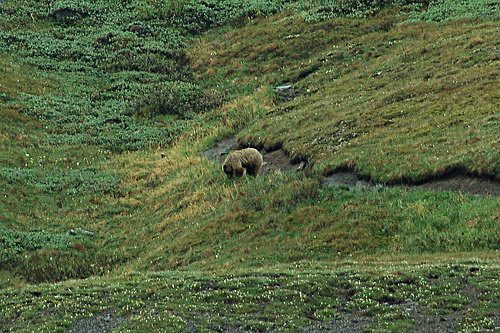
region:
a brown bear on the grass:
[218, 141, 266, 181]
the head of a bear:
[220, 155, 234, 182]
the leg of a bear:
[232, 161, 244, 181]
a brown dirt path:
[208, 117, 499, 203]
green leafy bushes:
[1, 0, 288, 155]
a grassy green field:
[186, 10, 498, 184]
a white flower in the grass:
[368, 296, 382, 313]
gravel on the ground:
[36, 300, 462, 332]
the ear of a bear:
[219, 160, 231, 172]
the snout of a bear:
[221, 170, 234, 180]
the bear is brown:
[208, 133, 288, 203]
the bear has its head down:
[204, 141, 286, 208]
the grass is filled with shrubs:
[2, 1, 491, 134]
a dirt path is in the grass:
[188, 117, 498, 254]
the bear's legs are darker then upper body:
[201, 136, 281, 207]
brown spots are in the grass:
[184, 0, 419, 100]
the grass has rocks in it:
[79, 298, 495, 331]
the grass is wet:
[0, 0, 496, 328]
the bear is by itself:
[182, 128, 279, 208]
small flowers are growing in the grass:
[3, 251, 487, 327]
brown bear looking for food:
[222, 148, 263, 180]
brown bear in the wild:
[5, 2, 495, 326]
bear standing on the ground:
[10, 7, 494, 324]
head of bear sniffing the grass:
[221, 162, 233, 179]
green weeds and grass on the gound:
[4, 1, 498, 263]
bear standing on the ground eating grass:
[220, 146, 262, 178]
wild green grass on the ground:
[2, 0, 207, 155]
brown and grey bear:
[0, 6, 498, 260]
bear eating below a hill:
[7, 106, 496, 201]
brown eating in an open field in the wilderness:
[8, 8, 495, 328]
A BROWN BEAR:
[216, 149, 286, 196]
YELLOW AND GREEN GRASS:
[110, 125, 224, 215]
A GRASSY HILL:
[298, 73, 467, 259]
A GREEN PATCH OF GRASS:
[12, 82, 139, 142]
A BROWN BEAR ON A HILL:
[216, 145, 276, 175]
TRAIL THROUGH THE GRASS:
[321, 152, 450, 206]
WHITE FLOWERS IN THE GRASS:
[338, 257, 429, 324]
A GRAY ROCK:
[268, 77, 293, 99]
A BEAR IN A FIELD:
[192, 140, 322, 205]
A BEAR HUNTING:
[218, 152, 288, 179]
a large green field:
[0, 3, 495, 326]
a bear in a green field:
[36, 6, 495, 331]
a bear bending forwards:
[214, 144, 271, 183]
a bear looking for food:
[215, 146, 266, 185]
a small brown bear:
[217, 148, 266, 181]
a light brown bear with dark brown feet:
[215, 146, 268, 180]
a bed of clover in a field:
[23, 0, 215, 130]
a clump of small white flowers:
[467, 313, 492, 330]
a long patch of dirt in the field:
[275, 149, 495, 204]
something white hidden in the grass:
[275, 81, 292, 92]